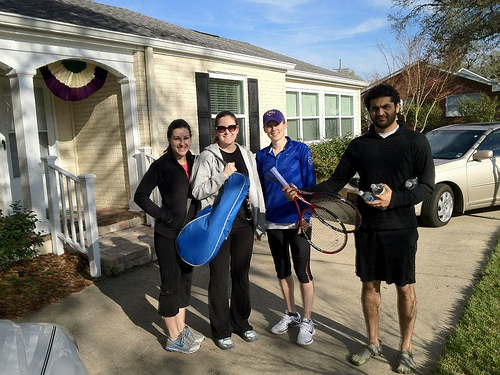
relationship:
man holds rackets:
[328, 75, 427, 359] [266, 155, 364, 254]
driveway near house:
[408, 242, 472, 308] [10, 3, 362, 220]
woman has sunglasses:
[195, 108, 284, 355] [220, 130, 248, 148]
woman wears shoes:
[195, 108, 284, 355] [215, 326, 259, 349]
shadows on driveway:
[65, 198, 278, 368] [408, 242, 472, 308]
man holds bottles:
[328, 75, 427, 359] [351, 169, 394, 222]